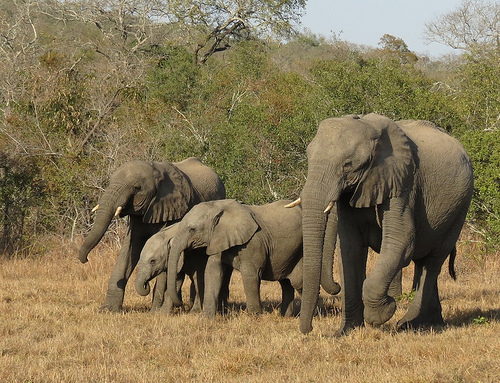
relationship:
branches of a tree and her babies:
[176, 0, 306, 76] [131, 182, 317, 323]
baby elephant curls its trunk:
[167, 191, 351, 326] [129, 264, 153, 300]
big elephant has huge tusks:
[282, 108, 488, 340] [65, 170, 207, 322]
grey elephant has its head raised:
[77, 153, 233, 331] [76, 170, 150, 269]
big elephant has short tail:
[282, 108, 488, 340] [446, 237, 472, 291]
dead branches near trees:
[87, 17, 148, 102] [3, 5, 99, 181]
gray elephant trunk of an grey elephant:
[163, 232, 191, 311] [77, 153, 233, 331]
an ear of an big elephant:
[144, 160, 192, 223] [282, 108, 488, 340]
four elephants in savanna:
[72, 109, 482, 332] [27, 15, 403, 376]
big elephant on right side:
[260, 90, 489, 330] [378, 11, 476, 380]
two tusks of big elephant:
[278, 185, 352, 225] [282, 108, 488, 340]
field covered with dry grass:
[13, 264, 435, 378] [53, 316, 194, 380]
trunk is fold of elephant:
[132, 265, 165, 309] [79, 157, 233, 313]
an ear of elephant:
[140, 160, 193, 225] [298, 112, 475, 341]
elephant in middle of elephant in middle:
[131, 190, 311, 330] [131, 190, 328, 331]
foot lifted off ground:
[357, 256, 411, 333] [225, 310, 453, 380]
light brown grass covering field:
[227, 307, 377, 377] [0, 264, 500, 378]